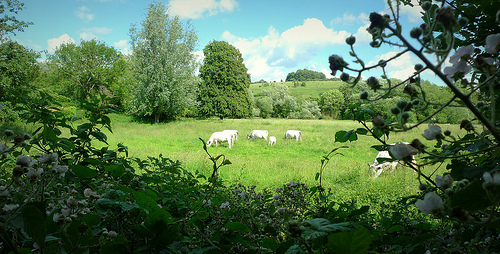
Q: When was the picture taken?
A: Daytime.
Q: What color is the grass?
A: Green.